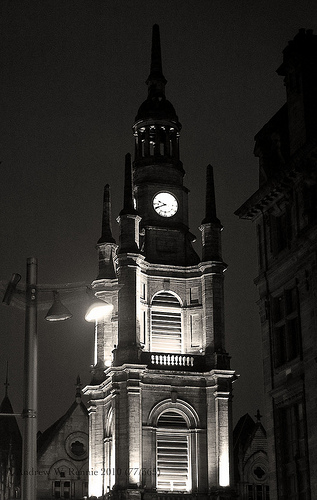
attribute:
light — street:
[87, 303, 113, 323]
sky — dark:
[229, 323, 260, 366]